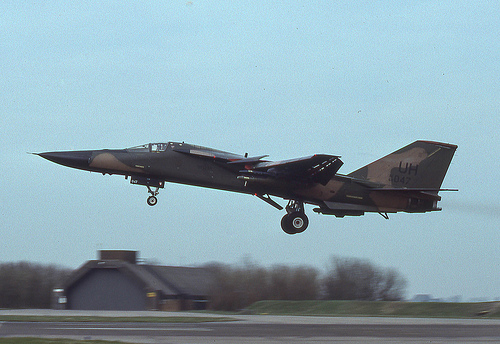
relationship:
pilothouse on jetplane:
[122, 137, 179, 153] [27, 138, 457, 234]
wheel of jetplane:
[265, 200, 343, 243] [22, 100, 449, 231]